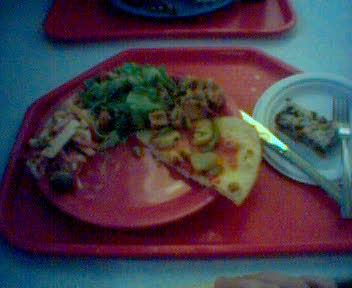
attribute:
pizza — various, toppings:
[133, 117, 261, 201]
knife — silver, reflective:
[237, 103, 340, 219]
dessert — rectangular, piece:
[279, 95, 338, 156]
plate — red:
[26, 68, 241, 226]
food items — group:
[139, 109, 265, 196]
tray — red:
[0, 46, 352, 255]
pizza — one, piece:
[62, 65, 261, 196]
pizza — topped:
[25, 60, 262, 206]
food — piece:
[132, 117, 279, 199]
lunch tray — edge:
[38, 2, 302, 42]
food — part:
[22, 57, 258, 208]